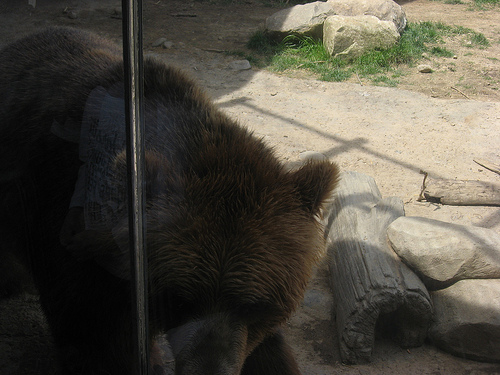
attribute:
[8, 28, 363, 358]
fur — brown, soft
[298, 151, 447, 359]
log — hallow, small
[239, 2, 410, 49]
stones — grey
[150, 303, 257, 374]
snout — black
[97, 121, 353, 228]
ears — brown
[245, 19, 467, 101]
grass — green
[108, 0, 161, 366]
pole — metal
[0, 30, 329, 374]
bear — enclosed, brown, large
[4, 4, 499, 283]
day — sunny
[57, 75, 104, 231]
sleeves — long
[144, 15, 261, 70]
rocks — small